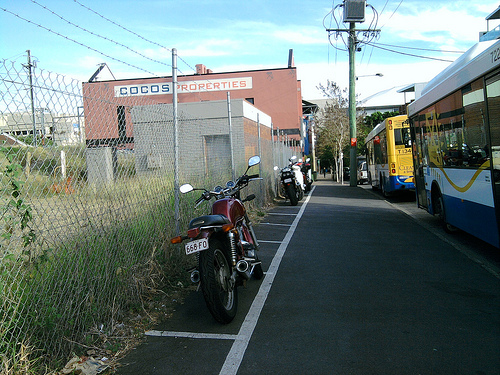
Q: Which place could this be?
A: It is a sidewalk.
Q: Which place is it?
A: It is a sidewalk.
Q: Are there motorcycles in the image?
A: Yes, there is a motorcycle.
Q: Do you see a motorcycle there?
A: Yes, there is a motorcycle.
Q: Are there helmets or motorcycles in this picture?
A: Yes, there is a motorcycle.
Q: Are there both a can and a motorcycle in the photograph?
A: No, there is a motorcycle but no cans.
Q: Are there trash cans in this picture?
A: No, there are no trash cans.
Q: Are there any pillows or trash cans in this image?
A: No, there are no trash cans or pillows.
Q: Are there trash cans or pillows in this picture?
A: No, there are no trash cans or pillows.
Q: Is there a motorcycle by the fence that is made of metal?
A: Yes, there is a motorcycle by the fence.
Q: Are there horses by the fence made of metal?
A: No, there is a motorcycle by the fence.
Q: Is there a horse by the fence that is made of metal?
A: No, there is a motorcycle by the fence.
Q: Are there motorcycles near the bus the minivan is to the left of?
A: Yes, there is a motorcycle near the bus.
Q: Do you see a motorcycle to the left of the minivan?
A: Yes, there is a motorcycle to the left of the minivan.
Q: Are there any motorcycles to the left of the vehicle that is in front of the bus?
A: Yes, there is a motorcycle to the left of the minivan.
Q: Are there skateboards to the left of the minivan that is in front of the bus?
A: No, there is a motorcycle to the left of the minivan.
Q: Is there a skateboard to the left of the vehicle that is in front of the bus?
A: No, there is a motorcycle to the left of the minivan.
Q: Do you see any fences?
A: Yes, there is a fence.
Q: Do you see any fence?
A: Yes, there is a fence.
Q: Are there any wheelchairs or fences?
A: Yes, there is a fence.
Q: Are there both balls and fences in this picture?
A: No, there is a fence but no balls.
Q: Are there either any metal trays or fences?
A: Yes, there is a metal fence.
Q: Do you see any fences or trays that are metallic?
A: Yes, the fence is metallic.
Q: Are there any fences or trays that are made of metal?
A: Yes, the fence is made of metal.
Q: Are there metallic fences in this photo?
A: Yes, there is a metal fence.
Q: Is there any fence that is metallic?
A: Yes, there is a fence that is metallic.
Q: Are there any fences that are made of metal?
A: Yes, there is a fence that is made of metal.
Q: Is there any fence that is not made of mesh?
A: Yes, there is a fence that is made of metal.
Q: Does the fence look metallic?
A: Yes, the fence is metallic.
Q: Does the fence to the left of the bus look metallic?
A: Yes, the fence is metallic.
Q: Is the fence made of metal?
A: Yes, the fence is made of metal.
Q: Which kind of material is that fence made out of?
A: The fence is made of metal.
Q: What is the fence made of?
A: The fence is made of metal.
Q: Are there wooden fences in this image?
A: No, there is a fence but it is metallic.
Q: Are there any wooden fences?
A: No, there is a fence but it is metallic.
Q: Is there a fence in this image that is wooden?
A: No, there is a fence but it is metallic.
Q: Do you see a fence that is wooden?
A: No, there is a fence but it is metallic.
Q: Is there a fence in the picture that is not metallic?
A: No, there is a fence but it is metallic.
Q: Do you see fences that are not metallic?
A: No, there is a fence but it is metallic.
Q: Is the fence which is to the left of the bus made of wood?
A: No, the fence is made of metal.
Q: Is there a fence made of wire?
A: No, there is a fence but it is made of metal.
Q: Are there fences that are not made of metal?
A: No, there is a fence but it is made of metal.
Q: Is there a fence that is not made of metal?
A: No, there is a fence but it is made of metal.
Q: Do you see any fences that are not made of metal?
A: No, there is a fence but it is made of metal.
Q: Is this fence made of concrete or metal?
A: The fence is made of metal.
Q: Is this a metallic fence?
A: Yes, this is a metallic fence.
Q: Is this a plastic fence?
A: No, this is a metallic fence.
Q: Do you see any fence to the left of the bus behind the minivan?
A: Yes, there is a fence to the left of the bus.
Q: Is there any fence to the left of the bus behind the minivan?
A: Yes, there is a fence to the left of the bus.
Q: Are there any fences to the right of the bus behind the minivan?
A: No, the fence is to the left of the bus.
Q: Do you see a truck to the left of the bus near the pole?
A: No, there is a fence to the left of the bus.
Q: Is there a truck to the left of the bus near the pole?
A: No, there is a fence to the left of the bus.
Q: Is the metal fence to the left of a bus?
A: Yes, the fence is to the left of a bus.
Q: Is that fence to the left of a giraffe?
A: No, the fence is to the left of a bus.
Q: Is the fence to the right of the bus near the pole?
A: No, the fence is to the left of the bus.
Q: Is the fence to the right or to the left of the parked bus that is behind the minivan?
A: The fence is to the left of the bus.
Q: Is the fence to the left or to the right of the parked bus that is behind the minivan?
A: The fence is to the left of the bus.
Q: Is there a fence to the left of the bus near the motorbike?
A: Yes, there is a fence to the left of the bus.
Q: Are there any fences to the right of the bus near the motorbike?
A: No, the fence is to the left of the bus.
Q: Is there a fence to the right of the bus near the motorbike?
A: No, the fence is to the left of the bus.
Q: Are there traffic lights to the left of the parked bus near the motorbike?
A: No, there is a fence to the left of the bus.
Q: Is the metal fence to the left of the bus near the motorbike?
A: Yes, the fence is to the left of the bus.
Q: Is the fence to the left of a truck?
A: No, the fence is to the left of the bus.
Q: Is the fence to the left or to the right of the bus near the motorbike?
A: The fence is to the left of the bus.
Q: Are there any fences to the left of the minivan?
A: Yes, there is a fence to the left of the minivan.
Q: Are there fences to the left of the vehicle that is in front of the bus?
A: Yes, there is a fence to the left of the minivan.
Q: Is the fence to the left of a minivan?
A: Yes, the fence is to the left of a minivan.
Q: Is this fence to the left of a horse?
A: No, the fence is to the left of a minivan.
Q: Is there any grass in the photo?
A: Yes, there is grass.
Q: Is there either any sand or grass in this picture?
A: Yes, there is grass.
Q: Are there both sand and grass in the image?
A: No, there is grass but no sand.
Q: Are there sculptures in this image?
A: No, there are no sculptures.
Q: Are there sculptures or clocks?
A: No, there are no sculptures or clocks.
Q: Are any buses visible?
A: Yes, there is a bus.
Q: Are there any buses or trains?
A: Yes, there is a bus.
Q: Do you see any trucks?
A: No, there are no trucks.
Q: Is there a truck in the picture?
A: No, there are no trucks.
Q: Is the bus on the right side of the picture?
A: Yes, the bus is on the right of the image.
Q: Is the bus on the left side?
A: No, the bus is on the right of the image.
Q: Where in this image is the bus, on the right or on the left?
A: The bus is on the right of the image.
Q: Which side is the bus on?
A: The bus is on the right of the image.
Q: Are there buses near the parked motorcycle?
A: Yes, there is a bus near the motorcycle.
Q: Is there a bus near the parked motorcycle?
A: Yes, there is a bus near the motorcycle.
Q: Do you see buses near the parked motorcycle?
A: Yes, there is a bus near the motorcycle.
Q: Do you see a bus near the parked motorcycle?
A: Yes, there is a bus near the motorcycle.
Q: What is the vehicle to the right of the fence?
A: The vehicle is a bus.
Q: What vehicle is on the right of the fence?
A: The vehicle is a bus.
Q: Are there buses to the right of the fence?
A: Yes, there is a bus to the right of the fence.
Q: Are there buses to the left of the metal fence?
A: No, the bus is to the right of the fence.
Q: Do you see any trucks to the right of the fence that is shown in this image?
A: No, there is a bus to the right of the fence.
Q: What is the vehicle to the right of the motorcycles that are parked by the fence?
A: The vehicle is a bus.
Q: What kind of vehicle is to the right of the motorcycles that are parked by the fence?
A: The vehicle is a bus.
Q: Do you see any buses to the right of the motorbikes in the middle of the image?
A: Yes, there is a bus to the right of the motorcycles.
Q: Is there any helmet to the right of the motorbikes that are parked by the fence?
A: No, there is a bus to the right of the motorcycles.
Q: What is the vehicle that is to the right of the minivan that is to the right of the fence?
A: The vehicle is a bus.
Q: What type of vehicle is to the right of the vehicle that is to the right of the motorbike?
A: The vehicle is a bus.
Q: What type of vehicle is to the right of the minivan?
A: The vehicle is a bus.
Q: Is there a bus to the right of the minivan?
A: Yes, there is a bus to the right of the minivan.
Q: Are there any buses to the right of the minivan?
A: Yes, there is a bus to the right of the minivan.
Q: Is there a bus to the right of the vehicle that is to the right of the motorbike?
A: Yes, there is a bus to the right of the minivan.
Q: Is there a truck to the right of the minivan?
A: No, there is a bus to the right of the minivan.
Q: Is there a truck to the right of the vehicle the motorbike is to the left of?
A: No, there is a bus to the right of the minivan.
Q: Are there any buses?
A: Yes, there is a bus.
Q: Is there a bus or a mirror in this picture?
A: Yes, there is a bus.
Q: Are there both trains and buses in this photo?
A: No, there is a bus but no trains.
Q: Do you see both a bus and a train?
A: No, there is a bus but no trains.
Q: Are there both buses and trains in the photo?
A: No, there is a bus but no trains.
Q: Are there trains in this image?
A: No, there are no trains.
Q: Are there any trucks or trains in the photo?
A: No, there are no trains or trucks.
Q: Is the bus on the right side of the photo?
A: Yes, the bus is on the right of the image.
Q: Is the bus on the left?
A: No, the bus is on the right of the image.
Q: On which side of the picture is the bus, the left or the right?
A: The bus is on the right of the image.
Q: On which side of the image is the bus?
A: The bus is on the right of the image.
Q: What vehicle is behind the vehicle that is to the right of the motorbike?
A: The vehicle is a bus.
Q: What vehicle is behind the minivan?
A: The vehicle is a bus.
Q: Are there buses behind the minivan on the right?
A: Yes, there is a bus behind the minivan.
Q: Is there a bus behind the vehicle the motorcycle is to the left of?
A: Yes, there is a bus behind the minivan.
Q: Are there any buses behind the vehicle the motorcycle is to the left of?
A: Yes, there is a bus behind the minivan.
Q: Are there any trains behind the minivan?
A: No, there is a bus behind the minivan.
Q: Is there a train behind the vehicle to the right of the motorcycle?
A: No, there is a bus behind the minivan.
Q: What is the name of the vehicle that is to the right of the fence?
A: The vehicle is a bus.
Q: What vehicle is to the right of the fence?
A: The vehicle is a bus.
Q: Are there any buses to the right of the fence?
A: Yes, there is a bus to the right of the fence.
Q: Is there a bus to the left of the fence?
A: No, the bus is to the right of the fence.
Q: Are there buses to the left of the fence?
A: No, the bus is to the right of the fence.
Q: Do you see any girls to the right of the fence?
A: No, there is a bus to the right of the fence.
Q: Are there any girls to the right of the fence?
A: No, there is a bus to the right of the fence.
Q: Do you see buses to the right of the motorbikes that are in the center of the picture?
A: Yes, there is a bus to the right of the motorcycles.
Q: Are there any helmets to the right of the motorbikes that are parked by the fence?
A: No, there is a bus to the right of the motorcycles.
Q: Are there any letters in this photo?
A: Yes, there are letters.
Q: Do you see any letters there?
A: Yes, there are letters.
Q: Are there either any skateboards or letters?
A: Yes, there are letters.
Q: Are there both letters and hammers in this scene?
A: No, there are letters but no hammers.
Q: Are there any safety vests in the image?
A: No, there are no safety vests.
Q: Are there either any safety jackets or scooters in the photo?
A: No, there are no safety jackets or scooters.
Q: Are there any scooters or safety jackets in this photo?
A: No, there are no safety jackets or scooters.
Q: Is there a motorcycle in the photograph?
A: Yes, there are motorcycles.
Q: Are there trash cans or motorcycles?
A: Yes, there are motorcycles.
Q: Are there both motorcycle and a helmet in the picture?
A: No, there are motorcycles but no helmets.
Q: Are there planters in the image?
A: No, there are no planters.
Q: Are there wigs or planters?
A: No, there are no planters or wigs.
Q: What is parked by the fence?
A: The motorcycles are parked by the fence.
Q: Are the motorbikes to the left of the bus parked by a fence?
A: Yes, the motorbikes are parked by a fence.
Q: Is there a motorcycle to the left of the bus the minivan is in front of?
A: Yes, there are motorcycles to the left of the bus.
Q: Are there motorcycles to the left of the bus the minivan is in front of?
A: Yes, there are motorcycles to the left of the bus.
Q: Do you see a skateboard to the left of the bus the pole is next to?
A: No, there are motorcycles to the left of the bus.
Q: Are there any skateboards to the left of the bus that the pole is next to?
A: No, there are motorcycles to the left of the bus.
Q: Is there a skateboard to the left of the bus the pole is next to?
A: No, there are motorcycles to the left of the bus.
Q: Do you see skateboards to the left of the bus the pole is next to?
A: No, there are motorcycles to the left of the bus.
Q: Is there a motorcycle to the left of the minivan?
A: Yes, there are motorcycles to the left of the minivan.